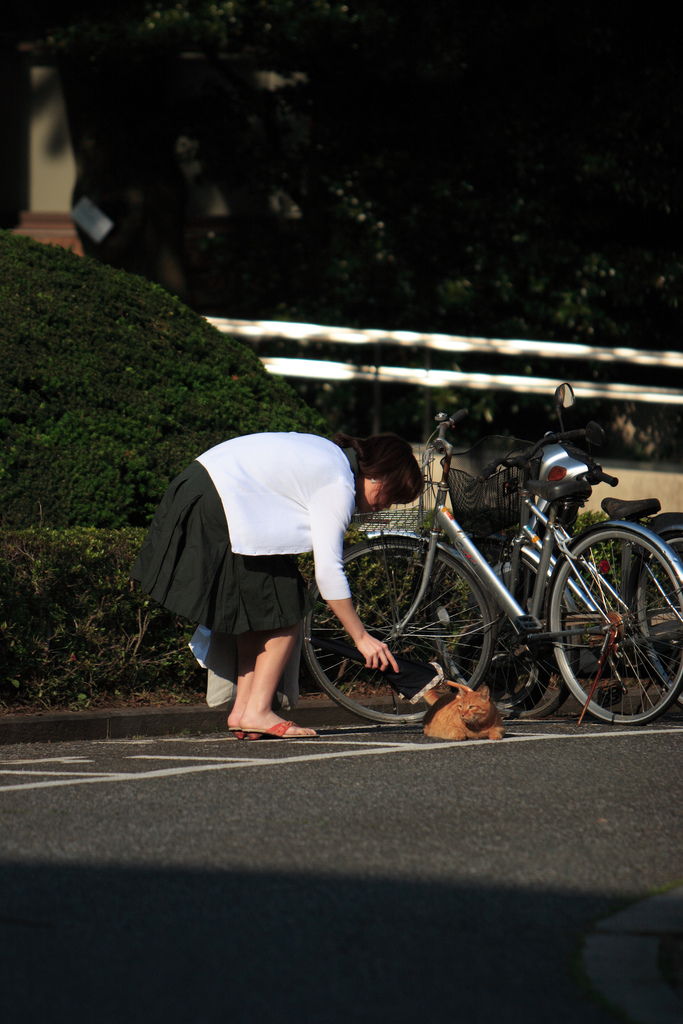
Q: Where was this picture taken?
A: On the street.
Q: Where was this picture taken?
A: On the street.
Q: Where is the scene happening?
A: Parking area.